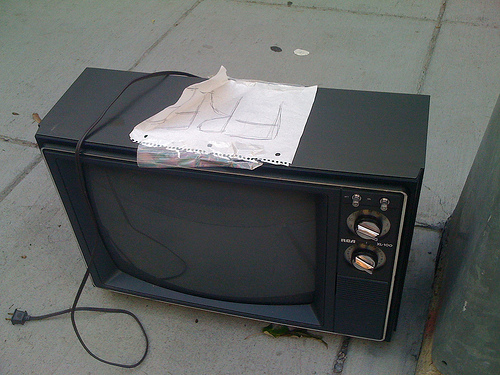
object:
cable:
[5, 269, 149, 368]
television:
[35, 58, 431, 343]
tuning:
[373, 193, 393, 213]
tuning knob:
[349, 189, 364, 209]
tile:
[122, 3, 442, 97]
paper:
[127, 65, 324, 168]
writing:
[159, 87, 289, 147]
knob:
[338, 240, 388, 276]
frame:
[30, 64, 431, 192]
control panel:
[330, 188, 404, 341]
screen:
[68, 154, 320, 304]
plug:
[2, 305, 30, 326]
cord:
[4, 69, 202, 368]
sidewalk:
[2, 3, 483, 373]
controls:
[342, 191, 399, 280]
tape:
[132, 143, 262, 173]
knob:
[348, 209, 387, 242]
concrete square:
[129, 3, 431, 97]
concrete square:
[0, 158, 398, 373]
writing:
[334, 232, 362, 254]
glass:
[82, 159, 321, 302]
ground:
[5, 0, 495, 373]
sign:
[126, 63, 319, 162]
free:
[141, 83, 291, 143]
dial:
[350, 215, 386, 245]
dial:
[349, 250, 380, 275]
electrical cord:
[2, 65, 198, 373]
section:
[114, 3, 455, 93]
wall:
[423, 105, 498, 372]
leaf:
[256, 318, 328, 348]